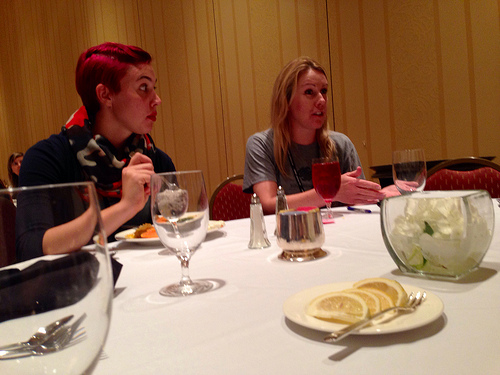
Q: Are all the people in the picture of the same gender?
A: Yes, all the people are female.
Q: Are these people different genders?
A: No, all the people are female.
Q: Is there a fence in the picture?
A: No, there are no fences.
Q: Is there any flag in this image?
A: No, there are no flags.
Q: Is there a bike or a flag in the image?
A: No, there are no flags or bikes.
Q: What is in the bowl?
A: The flowers are in the bowl.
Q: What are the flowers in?
A: The flowers are in the bowl.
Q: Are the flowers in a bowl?
A: Yes, the flowers are in a bowl.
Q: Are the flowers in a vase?
A: No, the flowers are in a bowl.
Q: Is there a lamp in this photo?
A: No, there are no lamps.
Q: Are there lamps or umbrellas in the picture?
A: No, there are no lamps or umbrellas.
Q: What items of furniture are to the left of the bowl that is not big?
A: The pieces of furniture are chairs.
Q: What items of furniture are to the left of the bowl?
A: The pieces of furniture are chairs.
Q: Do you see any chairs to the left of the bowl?
A: Yes, there are chairs to the left of the bowl.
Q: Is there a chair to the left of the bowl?
A: Yes, there are chairs to the left of the bowl.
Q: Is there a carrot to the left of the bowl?
A: No, there are chairs to the left of the bowl.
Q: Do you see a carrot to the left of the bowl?
A: No, there are chairs to the left of the bowl.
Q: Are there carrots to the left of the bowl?
A: No, there are chairs to the left of the bowl.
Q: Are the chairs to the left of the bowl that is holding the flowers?
A: Yes, the chairs are to the left of the bowl.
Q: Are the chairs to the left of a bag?
A: No, the chairs are to the left of the bowl.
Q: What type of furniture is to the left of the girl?
A: The pieces of furniture are chairs.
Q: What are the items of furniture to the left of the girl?
A: The pieces of furniture are chairs.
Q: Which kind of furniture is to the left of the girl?
A: The pieces of furniture are chairs.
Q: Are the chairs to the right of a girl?
A: No, the chairs are to the left of a girl.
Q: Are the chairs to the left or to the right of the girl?
A: The chairs are to the left of the girl.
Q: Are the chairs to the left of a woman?
A: No, the chairs are to the right of a woman.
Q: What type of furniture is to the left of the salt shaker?
A: The pieces of furniture are chairs.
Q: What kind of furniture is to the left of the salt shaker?
A: The pieces of furniture are chairs.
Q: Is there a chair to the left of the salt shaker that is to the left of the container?
A: Yes, there are chairs to the left of the salt shaker.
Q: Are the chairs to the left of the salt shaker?
A: Yes, the chairs are to the left of the salt shaker.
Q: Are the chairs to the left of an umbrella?
A: No, the chairs are to the left of the salt shaker.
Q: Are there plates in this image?
A: Yes, there is a plate.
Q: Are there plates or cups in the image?
A: Yes, there is a plate.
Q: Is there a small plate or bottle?
A: Yes, there is a small plate.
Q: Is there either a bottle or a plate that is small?
A: Yes, the plate is small.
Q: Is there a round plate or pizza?
A: Yes, there is a round plate.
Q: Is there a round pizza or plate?
A: Yes, there is a round plate.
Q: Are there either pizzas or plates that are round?
A: Yes, the plate is round.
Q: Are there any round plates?
A: Yes, there is a round plate.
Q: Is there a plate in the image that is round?
A: Yes, there is a plate that is round.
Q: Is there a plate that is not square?
A: Yes, there is a round plate.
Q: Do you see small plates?
A: Yes, there is a small plate.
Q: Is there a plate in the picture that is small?
A: Yes, there is a plate that is small.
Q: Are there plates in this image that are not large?
A: Yes, there is a small plate.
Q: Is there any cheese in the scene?
A: No, there is no cheese.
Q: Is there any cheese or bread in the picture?
A: No, there are no cheese or breads.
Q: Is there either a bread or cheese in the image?
A: No, there are no cheese or breads.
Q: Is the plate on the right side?
A: Yes, the plate is on the right of the image.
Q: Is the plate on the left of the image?
A: No, the plate is on the right of the image.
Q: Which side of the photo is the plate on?
A: The plate is on the right of the image.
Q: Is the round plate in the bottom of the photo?
A: Yes, the plate is in the bottom of the image.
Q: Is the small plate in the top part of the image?
A: No, the plate is in the bottom of the image.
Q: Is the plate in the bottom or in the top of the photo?
A: The plate is in the bottom of the image.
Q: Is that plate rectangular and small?
A: No, the plate is small but round.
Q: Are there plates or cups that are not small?
A: No, there is a plate but it is small.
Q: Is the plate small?
A: Yes, the plate is small.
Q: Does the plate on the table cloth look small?
A: Yes, the plate is small.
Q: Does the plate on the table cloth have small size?
A: Yes, the plate is small.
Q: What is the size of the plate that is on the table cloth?
A: The plate is small.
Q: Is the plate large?
A: No, the plate is small.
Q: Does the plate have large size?
A: No, the plate is small.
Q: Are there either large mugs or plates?
A: No, there is a plate but it is small.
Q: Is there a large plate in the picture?
A: No, there is a plate but it is small.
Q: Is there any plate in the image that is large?
A: No, there is a plate but it is small.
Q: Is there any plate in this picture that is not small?
A: No, there is a plate but it is small.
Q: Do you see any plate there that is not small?
A: No, there is a plate but it is small.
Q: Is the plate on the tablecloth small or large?
A: The plate is small.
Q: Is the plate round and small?
A: Yes, the plate is round and small.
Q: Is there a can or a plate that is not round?
A: No, there is a plate but it is round.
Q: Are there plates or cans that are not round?
A: No, there is a plate but it is round.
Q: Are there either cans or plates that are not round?
A: No, there is a plate but it is round.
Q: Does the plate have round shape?
A: Yes, the plate is round.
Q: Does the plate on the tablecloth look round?
A: Yes, the plate is round.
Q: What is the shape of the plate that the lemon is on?
A: The plate is round.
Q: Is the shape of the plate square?
A: No, the plate is round.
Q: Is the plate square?
A: No, the plate is round.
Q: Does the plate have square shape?
A: No, the plate is round.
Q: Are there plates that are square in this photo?
A: No, there is a plate but it is round.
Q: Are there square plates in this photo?
A: No, there is a plate but it is round.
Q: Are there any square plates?
A: No, there is a plate but it is round.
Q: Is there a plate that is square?
A: No, there is a plate but it is round.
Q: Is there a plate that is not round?
A: No, there is a plate but it is round.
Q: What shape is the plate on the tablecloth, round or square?
A: The plate is round.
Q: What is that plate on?
A: The plate is on the tablecloth.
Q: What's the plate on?
A: The plate is on the tablecloth.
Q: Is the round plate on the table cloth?
A: Yes, the plate is on the table cloth.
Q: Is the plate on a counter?
A: No, the plate is on the table cloth.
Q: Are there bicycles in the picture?
A: No, there are no bicycles.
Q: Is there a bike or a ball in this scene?
A: No, there are no bikes or balls.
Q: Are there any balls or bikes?
A: No, there are no bikes or balls.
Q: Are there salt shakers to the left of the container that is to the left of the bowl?
A: Yes, there is a salt shaker to the left of the container.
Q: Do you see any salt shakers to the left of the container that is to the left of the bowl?
A: Yes, there is a salt shaker to the left of the container.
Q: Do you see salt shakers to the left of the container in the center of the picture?
A: Yes, there is a salt shaker to the left of the container.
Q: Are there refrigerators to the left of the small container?
A: No, there is a salt shaker to the left of the container.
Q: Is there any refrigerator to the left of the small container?
A: No, there is a salt shaker to the left of the container.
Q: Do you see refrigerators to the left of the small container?
A: No, there is a salt shaker to the left of the container.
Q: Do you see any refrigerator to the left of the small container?
A: No, there is a salt shaker to the left of the container.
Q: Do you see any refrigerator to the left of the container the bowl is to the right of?
A: No, there is a salt shaker to the left of the container.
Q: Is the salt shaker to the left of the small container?
A: Yes, the salt shaker is to the left of the container.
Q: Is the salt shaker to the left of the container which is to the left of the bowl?
A: Yes, the salt shaker is to the left of the container.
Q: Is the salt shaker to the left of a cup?
A: No, the salt shaker is to the left of the container.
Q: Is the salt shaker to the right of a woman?
A: Yes, the salt shaker is to the right of a woman.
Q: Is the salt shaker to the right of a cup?
A: No, the salt shaker is to the right of a woman.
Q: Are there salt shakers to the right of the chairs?
A: Yes, there is a salt shaker to the right of the chairs.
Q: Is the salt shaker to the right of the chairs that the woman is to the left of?
A: Yes, the salt shaker is to the right of the chairs.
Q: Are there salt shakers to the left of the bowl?
A: Yes, there is a salt shaker to the left of the bowl.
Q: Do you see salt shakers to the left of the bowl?
A: Yes, there is a salt shaker to the left of the bowl.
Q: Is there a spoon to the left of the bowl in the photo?
A: No, there is a salt shaker to the left of the bowl.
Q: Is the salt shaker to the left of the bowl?
A: Yes, the salt shaker is to the left of the bowl.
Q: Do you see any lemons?
A: Yes, there is a lemon.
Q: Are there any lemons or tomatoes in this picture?
A: Yes, there is a lemon.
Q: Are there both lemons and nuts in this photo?
A: No, there is a lemon but no nuts.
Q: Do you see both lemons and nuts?
A: No, there is a lemon but no nuts.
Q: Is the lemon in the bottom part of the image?
A: Yes, the lemon is in the bottom of the image.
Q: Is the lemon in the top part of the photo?
A: No, the lemon is in the bottom of the image.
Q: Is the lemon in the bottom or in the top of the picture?
A: The lemon is in the bottom of the image.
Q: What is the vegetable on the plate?
A: The vegetable is a lemon.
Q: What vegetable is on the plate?
A: The vegetable is a lemon.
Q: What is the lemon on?
A: The lemon is on the plate.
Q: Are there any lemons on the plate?
A: Yes, there is a lemon on the plate.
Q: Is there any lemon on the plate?
A: Yes, there is a lemon on the plate.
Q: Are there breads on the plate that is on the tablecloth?
A: No, there is a lemon on the plate.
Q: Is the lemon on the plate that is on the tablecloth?
A: Yes, the lemon is on the plate.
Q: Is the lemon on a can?
A: No, the lemon is on the plate.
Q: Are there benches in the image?
A: No, there are no benches.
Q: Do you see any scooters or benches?
A: No, there are no benches or scooters.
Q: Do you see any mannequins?
A: No, there are no mannequins.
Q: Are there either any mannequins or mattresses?
A: No, there are no mannequins or mattresses.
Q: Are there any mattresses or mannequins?
A: No, there are no mannequins or mattresses.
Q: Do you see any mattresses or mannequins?
A: No, there are no mannequins or mattresses.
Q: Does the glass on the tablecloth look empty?
A: Yes, the glass is empty.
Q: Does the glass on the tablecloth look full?
A: No, the glass is empty.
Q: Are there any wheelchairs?
A: No, there are no wheelchairs.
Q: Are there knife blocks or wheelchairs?
A: No, there are no wheelchairs or knife blocks.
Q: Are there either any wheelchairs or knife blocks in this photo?
A: No, there are no wheelchairs or knife blocks.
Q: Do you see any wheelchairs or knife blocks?
A: No, there are no wheelchairs or knife blocks.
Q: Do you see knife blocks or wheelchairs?
A: No, there are no wheelchairs or knife blocks.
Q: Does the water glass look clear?
A: Yes, the glass is clear.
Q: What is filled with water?
A: The glass is filled with water.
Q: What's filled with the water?
A: The glass is filled with water.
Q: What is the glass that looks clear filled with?
A: The glass is filled with water.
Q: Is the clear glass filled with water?
A: Yes, the glass is filled with water.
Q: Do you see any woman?
A: Yes, there is a woman.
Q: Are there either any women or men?
A: Yes, there is a woman.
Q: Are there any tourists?
A: No, there are no tourists.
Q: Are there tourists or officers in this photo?
A: No, there are no tourists or officers.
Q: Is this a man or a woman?
A: This is a woman.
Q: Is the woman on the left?
A: Yes, the woman is on the left of the image.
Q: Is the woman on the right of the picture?
A: No, the woman is on the left of the image.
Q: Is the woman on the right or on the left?
A: The woman is on the left of the image.